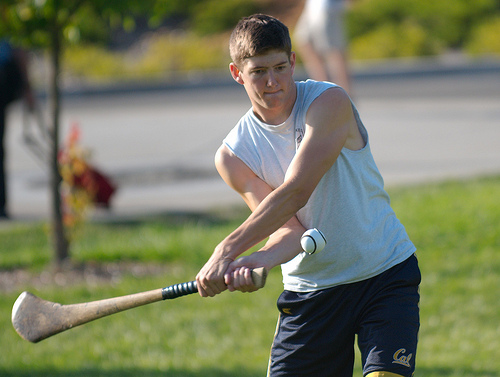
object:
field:
[3, 176, 497, 373]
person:
[290, 0, 350, 98]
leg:
[290, 10, 328, 81]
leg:
[310, 0, 350, 94]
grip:
[162, 281, 199, 300]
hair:
[228, 11, 292, 72]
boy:
[193, 10, 423, 377]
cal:
[391, 348, 413, 367]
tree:
[0, 0, 175, 268]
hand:
[195, 255, 233, 297]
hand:
[223, 255, 268, 293]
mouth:
[263, 89, 283, 95]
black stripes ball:
[299, 227, 328, 257]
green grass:
[420, 178, 499, 376]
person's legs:
[359, 293, 420, 377]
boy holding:
[193, 248, 279, 299]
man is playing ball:
[7, 8, 423, 377]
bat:
[10, 265, 268, 345]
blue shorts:
[265, 255, 424, 376]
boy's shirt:
[220, 76, 417, 293]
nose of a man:
[266, 71, 278, 88]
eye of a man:
[275, 65, 286, 71]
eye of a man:
[252, 69, 265, 74]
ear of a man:
[228, 62, 244, 85]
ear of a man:
[290, 53, 297, 77]